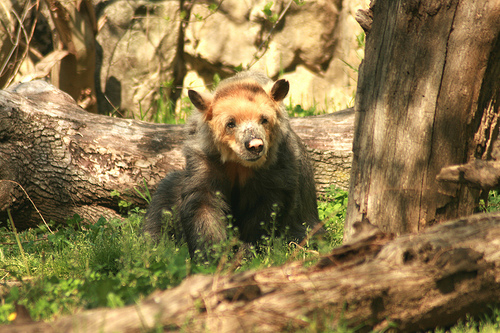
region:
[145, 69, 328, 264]
the brown bear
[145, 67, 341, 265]
the sitting brown bear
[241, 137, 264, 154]
the nose on the bear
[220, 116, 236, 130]
the right eye on the bear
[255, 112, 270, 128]
the left eye on the bear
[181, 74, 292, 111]
the ears on the bear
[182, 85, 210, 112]
the right ear on the bear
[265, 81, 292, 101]
the left ear on the bear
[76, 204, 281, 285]
the tall grass near the bear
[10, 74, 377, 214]
the large log behind the bear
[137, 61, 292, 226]
a bear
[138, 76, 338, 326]
a bear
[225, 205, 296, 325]
a bear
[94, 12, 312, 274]
a bear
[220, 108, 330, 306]
a bear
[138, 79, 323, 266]
a bear standing in the woods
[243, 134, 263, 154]
the nose of the bear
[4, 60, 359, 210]
the fallen tree behind the bear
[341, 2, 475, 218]
another tree standing by the bear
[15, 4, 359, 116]
the wall behind the bear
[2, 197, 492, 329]
another fallen log on the ground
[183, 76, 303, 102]
the ears of the bear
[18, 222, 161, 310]
the grass and weeds on the ground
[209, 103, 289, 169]
the face of the bear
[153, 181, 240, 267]
the leg of the bear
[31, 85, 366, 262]
the trunk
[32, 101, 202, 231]
the trunk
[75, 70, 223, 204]
the trunk